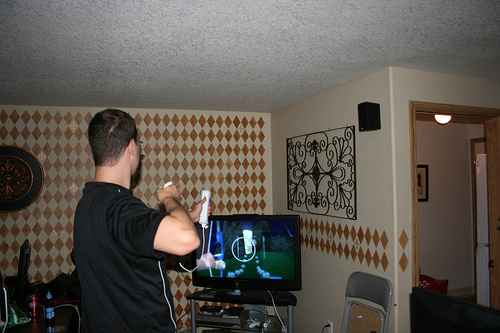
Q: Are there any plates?
A: No, there are no plates.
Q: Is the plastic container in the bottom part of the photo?
A: Yes, the container is in the bottom of the image.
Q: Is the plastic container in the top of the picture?
A: No, the container is in the bottom of the image.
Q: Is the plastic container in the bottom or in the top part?
A: The container is in the bottom of the image.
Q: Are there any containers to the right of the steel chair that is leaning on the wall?
A: Yes, there is a container to the right of the chair.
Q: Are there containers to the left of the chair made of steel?
A: No, the container is to the right of the chair.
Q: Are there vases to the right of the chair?
A: No, there is a container to the right of the chair.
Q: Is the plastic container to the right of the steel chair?
A: Yes, the container is to the right of the chair.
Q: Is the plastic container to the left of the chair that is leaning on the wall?
A: No, the container is to the right of the chair.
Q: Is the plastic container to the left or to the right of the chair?
A: The container is to the right of the chair.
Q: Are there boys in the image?
A: No, there are no boys.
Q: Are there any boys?
A: No, there are no boys.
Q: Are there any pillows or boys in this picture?
A: No, there are no boys or pillows.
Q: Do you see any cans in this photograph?
A: Yes, there is a can.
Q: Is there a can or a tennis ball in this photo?
A: Yes, there is a can.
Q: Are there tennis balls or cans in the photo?
A: Yes, there is a can.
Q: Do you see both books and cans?
A: No, there is a can but no books.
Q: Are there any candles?
A: No, there are no candles.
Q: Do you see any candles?
A: No, there are no candles.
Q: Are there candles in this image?
A: No, there are no candles.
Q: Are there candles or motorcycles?
A: No, there are no candles or motorcycles.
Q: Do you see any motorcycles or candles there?
A: No, there are no candles or motorcycles.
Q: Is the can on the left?
A: Yes, the can is on the left of the image.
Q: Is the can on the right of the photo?
A: No, the can is on the left of the image.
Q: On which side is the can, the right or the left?
A: The can is on the left of the image.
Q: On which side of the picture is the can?
A: The can is on the left of the image.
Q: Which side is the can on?
A: The can is on the left of the image.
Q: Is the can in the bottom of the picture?
A: Yes, the can is in the bottom of the image.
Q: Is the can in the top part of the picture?
A: No, the can is in the bottom of the image.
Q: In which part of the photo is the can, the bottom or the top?
A: The can is in the bottom of the image.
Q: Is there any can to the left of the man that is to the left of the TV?
A: Yes, there is a can to the left of the man.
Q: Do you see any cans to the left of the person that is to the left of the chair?
A: Yes, there is a can to the left of the man.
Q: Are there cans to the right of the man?
A: No, the can is to the left of the man.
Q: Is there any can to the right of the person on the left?
A: No, the can is to the left of the man.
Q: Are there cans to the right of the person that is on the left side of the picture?
A: No, the can is to the left of the man.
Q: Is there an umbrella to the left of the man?
A: No, there is a can to the left of the man.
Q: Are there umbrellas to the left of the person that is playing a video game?
A: No, there is a can to the left of the man.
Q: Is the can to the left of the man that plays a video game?
A: Yes, the can is to the left of the man.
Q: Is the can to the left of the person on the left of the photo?
A: Yes, the can is to the left of the man.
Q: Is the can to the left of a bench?
A: No, the can is to the left of the man.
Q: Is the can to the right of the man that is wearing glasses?
A: No, the can is to the left of the man.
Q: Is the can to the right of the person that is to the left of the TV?
A: No, the can is to the left of the man.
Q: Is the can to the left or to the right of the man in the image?
A: The can is to the left of the man.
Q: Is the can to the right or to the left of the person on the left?
A: The can is to the left of the man.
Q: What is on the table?
A: The can is on the table.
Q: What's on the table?
A: The can is on the table.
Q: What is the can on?
A: The can is on the table.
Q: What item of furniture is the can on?
A: The can is on the table.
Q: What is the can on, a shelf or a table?
A: The can is on a table.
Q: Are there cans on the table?
A: Yes, there is a can on the table.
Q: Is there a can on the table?
A: Yes, there is a can on the table.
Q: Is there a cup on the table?
A: No, there is a can on the table.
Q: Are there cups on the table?
A: No, there is a can on the table.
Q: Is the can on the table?
A: Yes, the can is on the table.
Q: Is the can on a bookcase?
A: No, the can is on the table.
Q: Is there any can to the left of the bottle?
A: Yes, there is a can to the left of the bottle.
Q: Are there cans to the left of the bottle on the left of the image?
A: Yes, there is a can to the left of the bottle.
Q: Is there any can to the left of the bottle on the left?
A: Yes, there is a can to the left of the bottle.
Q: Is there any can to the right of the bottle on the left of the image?
A: No, the can is to the left of the bottle.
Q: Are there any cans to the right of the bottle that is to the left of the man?
A: No, the can is to the left of the bottle.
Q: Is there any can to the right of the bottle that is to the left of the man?
A: No, the can is to the left of the bottle.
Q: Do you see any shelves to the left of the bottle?
A: No, there is a can to the left of the bottle.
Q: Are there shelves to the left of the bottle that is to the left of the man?
A: No, there is a can to the left of the bottle.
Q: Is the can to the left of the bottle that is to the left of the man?
A: Yes, the can is to the left of the bottle.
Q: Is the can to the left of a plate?
A: No, the can is to the left of the bottle.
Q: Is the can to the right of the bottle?
A: No, the can is to the left of the bottle.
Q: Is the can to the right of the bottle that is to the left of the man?
A: No, the can is to the left of the bottle.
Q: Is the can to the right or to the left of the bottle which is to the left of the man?
A: The can is to the left of the bottle.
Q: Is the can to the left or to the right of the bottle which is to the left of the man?
A: The can is to the left of the bottle.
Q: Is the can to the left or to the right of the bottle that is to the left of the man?
A: The can is to the left of the bottle.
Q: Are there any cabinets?
A: No, there are no cabinets.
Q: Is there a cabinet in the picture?
A: No, there are no cabinets.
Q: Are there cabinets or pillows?
A: No, there are no cabinets or pillows.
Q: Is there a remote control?
A: Yes, there is a remote control.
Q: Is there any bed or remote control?
A: Yes, there is a remote control.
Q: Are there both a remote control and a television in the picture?
A: Yes, there are both a remote control and a television.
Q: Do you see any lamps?
A: No, there are no lamps.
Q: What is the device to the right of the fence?
A: The device is a remote control.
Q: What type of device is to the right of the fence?
A: The device is a remote control.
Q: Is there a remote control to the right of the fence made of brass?
A: Yes, there is a remote control to the right of the fence.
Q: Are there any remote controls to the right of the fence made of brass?
A: Yes, there is a remote control to the right of the fence.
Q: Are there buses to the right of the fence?
A: No, there is a remote control to the right of the fence.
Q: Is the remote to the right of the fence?
A: Yes, the remote is to the right of the fence.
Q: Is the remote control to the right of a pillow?
A: No, the remote control is to the right of the fence.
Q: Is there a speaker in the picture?
A: Yes, there is a speaker.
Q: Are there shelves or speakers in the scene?
A: Yes, there is a speaker.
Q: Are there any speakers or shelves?
A: Yes, there is a speaker.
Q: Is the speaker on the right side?
A: Yes, the speaker is on the right of the image.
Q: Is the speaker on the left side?
A: No, the speaker is on the right of the image.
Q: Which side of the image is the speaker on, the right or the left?
A: The speaker is on the right of the image.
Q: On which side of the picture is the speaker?
A: The speaker is on the right of the image.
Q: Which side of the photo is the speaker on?
A: The speaker is on the right of the image.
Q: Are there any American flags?
A: No, there are no American flags.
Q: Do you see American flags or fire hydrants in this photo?
A: No, there are no American flags or fire hydrants.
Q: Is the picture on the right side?
A: Yes, the picture is on the right of the image.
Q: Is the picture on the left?
A: No, the picture is on the right of the image.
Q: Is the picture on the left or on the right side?
A: The picture is on the right of the image.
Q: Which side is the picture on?
A: The picture is on the right of the image.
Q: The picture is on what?
A: The picture is on the wall.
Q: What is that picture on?
A: The picture is on the wall.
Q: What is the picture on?
A: The picture is on the wall.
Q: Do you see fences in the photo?
A: Yes, there is a fence.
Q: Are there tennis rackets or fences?
A: Yes, there is a fence.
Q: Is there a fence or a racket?
A: Yes, there is a fence.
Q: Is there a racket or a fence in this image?
A: Yes, there is a fence.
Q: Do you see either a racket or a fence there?
A: Yes, there is a fence.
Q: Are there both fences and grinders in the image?
A: No, there is a fence but no grinders.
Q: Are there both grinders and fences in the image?
A: No, there is a fence but no grinders.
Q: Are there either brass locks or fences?
A: Yes, there is a brass fence.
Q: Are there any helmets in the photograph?
A: No, there are no helmets.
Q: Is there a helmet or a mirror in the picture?
A: No, there are no helmets or mirrors.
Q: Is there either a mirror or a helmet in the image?
A: No, there are no helmets or mirrors.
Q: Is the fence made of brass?
A: Yes, the fence is made of brass.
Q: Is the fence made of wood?
A: No, the fence is made of brass.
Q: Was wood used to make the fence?
A: No, the fence is made of brass.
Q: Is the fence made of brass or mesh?
A: The fence is made of brass.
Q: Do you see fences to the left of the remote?
A: Yes, there is a fence to the left of the remote.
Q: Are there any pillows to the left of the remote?
A: No, there is a fence to the left of the remote.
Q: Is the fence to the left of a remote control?
A: Yes, the fence is to the left of a remote control.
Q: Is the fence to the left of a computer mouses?
A: No, the fence is to the left of a remote control.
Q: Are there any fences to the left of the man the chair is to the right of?
A: Yes, there is a fence to the left of the man.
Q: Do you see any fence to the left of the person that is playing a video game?
A: Yes, there is a fence to the left of the man.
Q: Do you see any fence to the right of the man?
A: No, the fence is to the left of the man.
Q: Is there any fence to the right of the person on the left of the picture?
A: No, the fence is to the left of the man.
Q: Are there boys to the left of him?
A: No, there is a fence to the left of the man.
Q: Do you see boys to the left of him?
A: No, there is a fence to the left of the man.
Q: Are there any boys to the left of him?
A: No, there is a fence to the left of the man.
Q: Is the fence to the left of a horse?
A: No, the fence is to the left of the man.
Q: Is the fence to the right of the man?
A: No, the fence is to the left of the man.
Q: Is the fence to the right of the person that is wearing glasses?
A: No, the fence is to the left of the man.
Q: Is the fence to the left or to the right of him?
A: The fence is to the left of the man.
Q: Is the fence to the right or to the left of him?
A: The fence is to the left of the man.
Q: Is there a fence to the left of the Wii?
A: Yes, there is a fence to the left of the Wii.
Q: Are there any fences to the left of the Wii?
A: Yes, there is a fence to the left of the Wii.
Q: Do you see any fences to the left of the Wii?
A: Yes, there is a fence to the left of the Wii.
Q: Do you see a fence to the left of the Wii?
A: Yes, there is a fence to the left of the Wii.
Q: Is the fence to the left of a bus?
A: No, the fence is to the left of the Wii.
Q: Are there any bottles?
A: Yes, there is a bottle.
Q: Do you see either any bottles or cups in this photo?
A: Yes, there is a bottle.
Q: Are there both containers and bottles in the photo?
A: Yes, there are both a bottle and containers.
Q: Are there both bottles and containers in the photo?
A: Yes, there are both a bottle and containers.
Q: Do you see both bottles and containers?
A: Yes, there are both a bottle and containers.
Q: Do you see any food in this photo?
A: No, there is no food.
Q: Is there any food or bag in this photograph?
A: No, there are no food or bags.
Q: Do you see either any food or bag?
A: No, there are no food or bags.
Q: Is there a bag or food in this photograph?
A: No, there are no food or bags.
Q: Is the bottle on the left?
A: Yes, the bottle is on the left of the image.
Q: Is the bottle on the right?
A: No, the bottle is on the left of the image.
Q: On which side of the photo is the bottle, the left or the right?
A: The bottle is on the left of the image.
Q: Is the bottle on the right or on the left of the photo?
A: The bottle is on the left of the image.